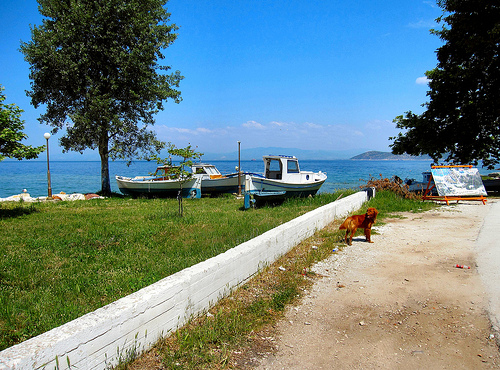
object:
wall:
[35, 177, 382, 367]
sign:
[433, 168, 485, 195]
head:
[365, 207, 379, 219]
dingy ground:
[270, 200, 500, 369]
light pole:
[46, 139, 52, 198]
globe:
[43, 132, 51, 139]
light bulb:
[43, 132, 51, 139]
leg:
[366, 226, 372, 240]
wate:
[350, 147, 410, 165]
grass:
[81, 221, 162, 276]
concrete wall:
[0, 186, 375, 368]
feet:
[368, 240, 375, 243]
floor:
[350, 276, 459, 357]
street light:
[43, 132, 54, 198]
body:
[339, 208, 381, 246]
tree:
[15, 1, 183, 198]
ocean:
[336, 160, 412, 170]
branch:
[359, 173, 422, 200]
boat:
[243, 153, 328, 207]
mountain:
[350, 150, 412, 160]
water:
[334, 166, 361, 180]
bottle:
[455, 264, 471, 270]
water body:
[0, 148, 499, 184]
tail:
[339, 216, 353, 230]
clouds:
[187, 108, 393, 145]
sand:
[284, 337, 313, 358]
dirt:
[399, 313, 411, 327]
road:
[0, 193, 500, 368]